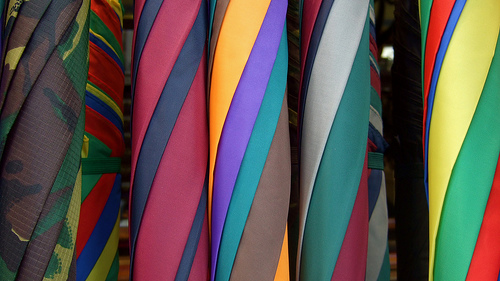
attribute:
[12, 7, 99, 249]
fabric — green and brown, camoflauged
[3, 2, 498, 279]
umbrellas — multi-colored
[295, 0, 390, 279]
tie — multicolored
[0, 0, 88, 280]
tie — multicolored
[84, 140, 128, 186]
cloth — green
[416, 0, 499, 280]
umbrella — red, yellow, green, blue, brightly colored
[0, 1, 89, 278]
umbrella — green, brown, camouflage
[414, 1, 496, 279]
tie — multicolored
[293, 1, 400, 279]
tie — multicolored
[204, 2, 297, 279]
tie — multicolored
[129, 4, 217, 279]
tie — multicolored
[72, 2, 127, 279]
tie — multicolored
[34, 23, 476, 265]
ties — colorful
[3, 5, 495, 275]
fabric — multicolored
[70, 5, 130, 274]
umbrella — red, blue, yellow, green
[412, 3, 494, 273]
stripe — YELLOW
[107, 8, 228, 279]
umbrella. — pink, blue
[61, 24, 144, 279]
cloth — twisted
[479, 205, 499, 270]
stripe — red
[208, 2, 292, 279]
striped fabric — yellow purple blue and brown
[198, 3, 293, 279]
umbrella — yellow, purple, green, gray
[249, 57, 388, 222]
fabric — striped, blue red white and teel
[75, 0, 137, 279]
tie — red and blue, striped